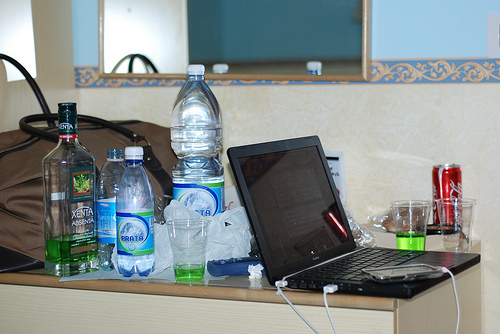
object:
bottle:
[167, 60, 227, 219]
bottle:
[112, 141, 157, 279]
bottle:
[92, 145, 129, 272]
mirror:
[105, 1, 366, 77]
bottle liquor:
[41, 230, 96, 276]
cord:
[273, 278, 315, 332]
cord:
[318, 281, 340, 332]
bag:
[2, 53, 192, 272]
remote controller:
[207, 255, 264, 277]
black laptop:
[225, 133, 480, 301]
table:
[0, 222, 480, 332]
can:
[427, 163, 465, 226]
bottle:
[44, 99, 100, 278]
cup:
[167, 217, 215, 287]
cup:
[389, 198, 433, 250]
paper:
[247, 259, 266, 283]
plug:
[321, 283, 343, 331]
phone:
[359, 260, 443, 283]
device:
[362, 263, 448, 283]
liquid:
[171, 264, 206, 281]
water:
[168, 85, 218, 210]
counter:
[0, 261, 481, 331]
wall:
[69, 0, 500, 157]